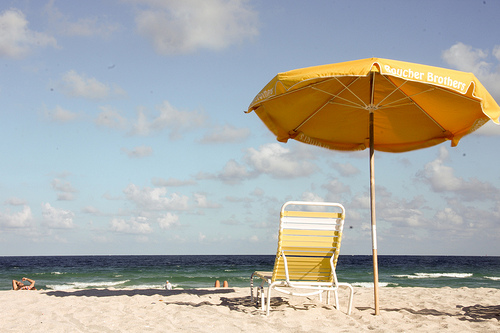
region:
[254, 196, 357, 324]
yellow and white chair on beach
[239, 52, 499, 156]
yellow umbrella by chair on beach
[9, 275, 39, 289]
a sunbather laying on beach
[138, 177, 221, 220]
sky and clouds over the beach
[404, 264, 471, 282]
ocean wave breaking on beach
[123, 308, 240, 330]
sand by chair on beach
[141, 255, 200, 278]
ocean changing colors in background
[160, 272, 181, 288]
someone close to ocean on beach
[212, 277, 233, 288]
pair of knees of a sunbather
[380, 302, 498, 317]
shadow of yellow beach umbrella in sand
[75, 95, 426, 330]
A waterfront beach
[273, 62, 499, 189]
A yellow umbrella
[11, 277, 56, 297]
A person sunbathing.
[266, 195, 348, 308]
A yellow and white lawn chair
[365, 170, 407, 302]
The umbrella pole is wood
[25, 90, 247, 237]
There white clouds in the sky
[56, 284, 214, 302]
a shadow of the umbrella on the sand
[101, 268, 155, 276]
A water is green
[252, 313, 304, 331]
Sand with foot prints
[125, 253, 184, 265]
the water is blue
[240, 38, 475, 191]
yellow umbrella on the beach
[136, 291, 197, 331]
brown sand on the beach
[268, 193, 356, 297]
yellow and white chair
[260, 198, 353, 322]
chair facing the water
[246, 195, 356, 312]
chair on the sand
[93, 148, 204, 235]
blue sky above the ocean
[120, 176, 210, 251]
white clouds in the sky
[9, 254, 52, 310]
person on the beach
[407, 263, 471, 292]
waves coming to shore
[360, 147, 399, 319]
pole holding up umbrella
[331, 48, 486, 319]
Yellow umbrella in the sand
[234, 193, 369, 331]
Yellow and white chair on the beach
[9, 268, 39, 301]
Person laying on the beach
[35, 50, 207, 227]
Pale blue sky with clouds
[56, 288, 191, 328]
Beige sand on the beach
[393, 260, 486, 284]
White caps on the water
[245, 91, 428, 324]
Umbrella and chair on the beach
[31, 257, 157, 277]
Dark water of the ocean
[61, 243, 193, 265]
Horizon line over the ocean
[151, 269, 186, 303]
Bird on the beach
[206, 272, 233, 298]
the knees of someone laying on the sand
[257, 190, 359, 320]
a yellow and white beach chair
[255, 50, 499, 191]
a yellow beach parasol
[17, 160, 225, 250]
scattered clouds in the sky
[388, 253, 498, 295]
the gentle waves of the ocean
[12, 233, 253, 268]
the blue horizon of the ocean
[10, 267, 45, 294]
a person lying on the beach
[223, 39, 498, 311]
a beach chair and a beach parasol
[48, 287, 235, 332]
shadows on the sand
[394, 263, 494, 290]
the white foam of the surf